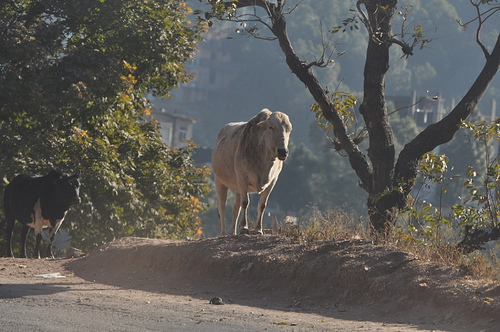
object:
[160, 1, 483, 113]
haze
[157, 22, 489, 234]
mountain side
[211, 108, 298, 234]
cow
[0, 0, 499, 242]
hill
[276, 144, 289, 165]
nose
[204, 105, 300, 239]
cow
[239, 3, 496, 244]
tree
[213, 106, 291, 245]
cow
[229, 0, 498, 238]
tree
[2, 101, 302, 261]
cows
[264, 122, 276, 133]
eye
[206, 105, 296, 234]
cow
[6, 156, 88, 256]
cow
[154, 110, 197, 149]
house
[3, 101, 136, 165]
leaves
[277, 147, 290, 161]
nose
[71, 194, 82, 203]
nose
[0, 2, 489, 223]
trees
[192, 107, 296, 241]
cow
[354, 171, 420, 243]
tree trunk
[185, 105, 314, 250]
cow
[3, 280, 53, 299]
shadow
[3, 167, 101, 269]
cow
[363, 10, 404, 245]
tree trunk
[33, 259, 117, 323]
dirt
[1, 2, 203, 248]
tree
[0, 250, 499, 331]
sandy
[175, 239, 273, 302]
dirt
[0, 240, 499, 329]
ground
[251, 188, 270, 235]
leg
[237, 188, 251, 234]
leg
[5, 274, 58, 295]
shadow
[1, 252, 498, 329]
road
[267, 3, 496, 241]
tree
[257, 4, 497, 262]
tree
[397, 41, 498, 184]
branch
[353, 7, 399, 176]
branch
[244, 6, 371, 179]
branch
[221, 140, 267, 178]
fur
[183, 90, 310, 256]
cow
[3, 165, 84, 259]
cow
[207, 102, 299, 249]
cow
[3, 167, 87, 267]
cow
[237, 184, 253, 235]
right leg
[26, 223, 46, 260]
right leg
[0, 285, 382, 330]
sand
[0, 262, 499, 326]
ground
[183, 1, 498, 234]
hill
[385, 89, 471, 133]
house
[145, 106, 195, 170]
house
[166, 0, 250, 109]
house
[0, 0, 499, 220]
hill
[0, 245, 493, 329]
dirt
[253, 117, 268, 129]
ear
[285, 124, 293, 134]
eye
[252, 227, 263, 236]
hoof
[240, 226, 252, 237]
hoof